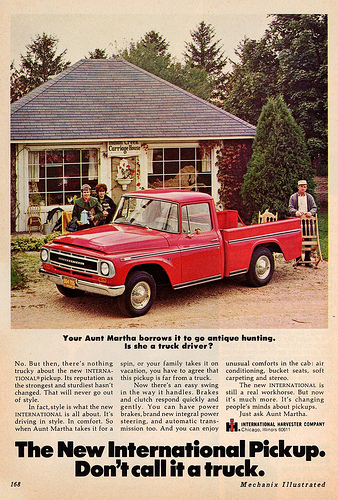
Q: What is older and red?
A: Truck.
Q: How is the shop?
A: Cottage-like.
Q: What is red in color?
A: The truck.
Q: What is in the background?
A: Trees.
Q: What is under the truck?
A: Dirt.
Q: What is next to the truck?
A: A building.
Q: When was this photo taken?
A: During the day.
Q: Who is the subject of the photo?
A: The truck.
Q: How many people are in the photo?
A: 3.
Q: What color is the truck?
A: Red.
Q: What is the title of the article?
A: The New International Pickup. Don't Call It A Truck.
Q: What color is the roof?
A: Gray.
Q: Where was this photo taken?
A: At an antique shop.